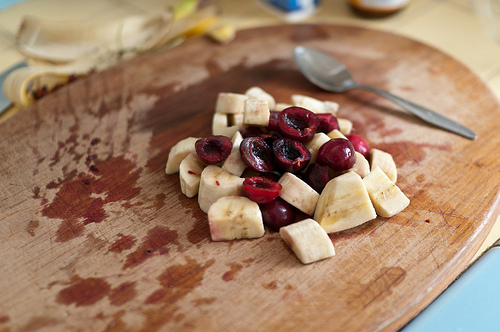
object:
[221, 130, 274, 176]
bananas & cherries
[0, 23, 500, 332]
cutting board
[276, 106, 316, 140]
cherry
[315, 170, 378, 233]
banana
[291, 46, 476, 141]
spoon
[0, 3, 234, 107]
banana peel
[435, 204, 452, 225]
scratches & scuffs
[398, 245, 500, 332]
countertop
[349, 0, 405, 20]
jar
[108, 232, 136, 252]
cherry juice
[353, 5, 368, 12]
edge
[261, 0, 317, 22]
container